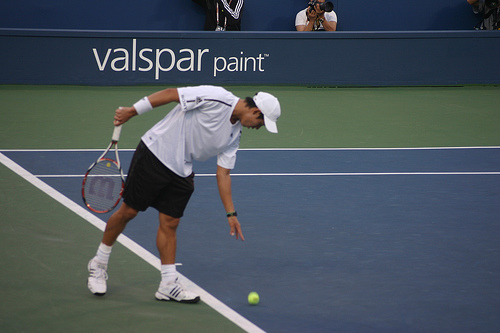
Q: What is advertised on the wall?
A: Valspar paint.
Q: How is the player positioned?
A: Bending down.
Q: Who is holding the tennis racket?
A: The man.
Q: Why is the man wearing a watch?
A: To tell time.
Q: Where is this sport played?
A: A tennis court.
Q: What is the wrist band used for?
A: To wipe sweat.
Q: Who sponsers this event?
A: Valspar Paint.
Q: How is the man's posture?
A: Bent.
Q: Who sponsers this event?
A: Valspar Paint.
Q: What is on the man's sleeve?
A: A stripe.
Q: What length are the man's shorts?
A: Knee length.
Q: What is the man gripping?
A: Tennis racket.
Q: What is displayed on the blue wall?
A: The advertisement.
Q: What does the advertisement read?
A: Valspar paint.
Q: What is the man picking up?
A: A tennis ball.